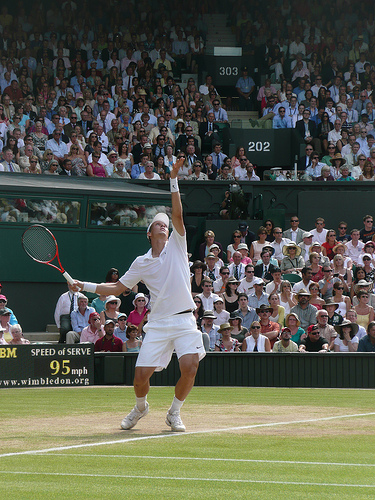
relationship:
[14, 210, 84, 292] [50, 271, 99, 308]
racquet in hand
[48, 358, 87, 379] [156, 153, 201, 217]
shows speed of serve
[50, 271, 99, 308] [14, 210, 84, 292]
hand holding racket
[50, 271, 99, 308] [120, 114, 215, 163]
hand in air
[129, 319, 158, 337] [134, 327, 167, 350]
ball in pocket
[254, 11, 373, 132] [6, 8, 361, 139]
section of stadium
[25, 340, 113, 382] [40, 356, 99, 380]
sign that shows speed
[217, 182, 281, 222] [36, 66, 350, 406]
camera person recording match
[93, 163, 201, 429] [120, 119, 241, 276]
man going to serve ball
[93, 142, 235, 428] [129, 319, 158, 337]
man hitting ball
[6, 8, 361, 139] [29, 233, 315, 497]
crowd watching game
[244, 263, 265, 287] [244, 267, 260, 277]
man wearing sunglasses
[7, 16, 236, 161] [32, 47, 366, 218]
spectators watching activity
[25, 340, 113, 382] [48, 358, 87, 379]
sign announcing shows speed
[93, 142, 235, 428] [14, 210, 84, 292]
man holding racket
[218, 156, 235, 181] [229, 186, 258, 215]
person behind camera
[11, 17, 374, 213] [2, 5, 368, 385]
people in stands